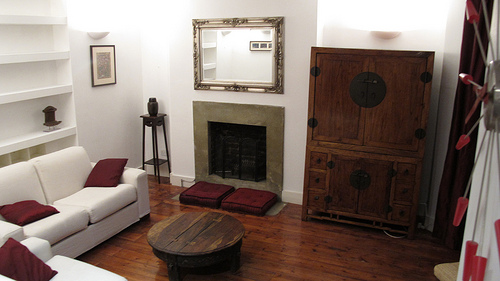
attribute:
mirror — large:
[193, 17, 285, 94]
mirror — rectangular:
[187, 12, 288, 96]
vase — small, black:
[148, 96, 160, 118]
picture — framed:
[83, 39, 138, 84]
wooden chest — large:
[280, 31, 442, 250]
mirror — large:
[191, 12, 300, 99]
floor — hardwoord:
[75, 164, 458, 279]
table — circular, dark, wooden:
[146, 209, 248, 278]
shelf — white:
[3, 5, 79, 158]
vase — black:
[142, 93, 167, 120]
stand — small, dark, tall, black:
[139, 111, 172, 185]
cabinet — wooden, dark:
[298, 45, 435, 242]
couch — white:
[4, 134, 152, 279]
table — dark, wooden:
[140, 112, 170, 182]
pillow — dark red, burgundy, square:
[85, 155, 129, 186]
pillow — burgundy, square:
[0, 199, 59, 229]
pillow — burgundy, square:
[2, 237, 59, 280]